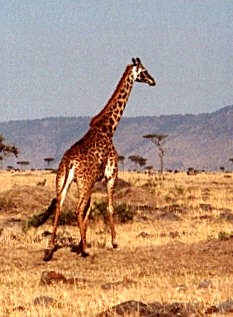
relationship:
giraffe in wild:
[34, 54, 166, 259] [1, 2, 231, 316]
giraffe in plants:
[34, 54, 166, 259] [0, 166, 233, 316]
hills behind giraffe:
[2, 101, 232, 166] [34, 54, 166, 259]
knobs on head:
[130, 56, 143, 65] [130, 64, 157, 84]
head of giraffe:
[130, 64, 157, 84] [34, 54, 166, 259]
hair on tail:
[30, 198, 58, 225] [30, 164, 71, 224]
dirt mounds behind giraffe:
[5, 175, 154, 218] [34, 54, 166, 259]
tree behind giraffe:
[141, 129, 169, 173] [34, 54, 166, 259]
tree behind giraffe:
[44, 158, 58, 171] [34, 54, 166, 259]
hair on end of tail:
[30, 198, 58, 225] [30, 164, 71, 224]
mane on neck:
[89, 65, 130, 126] [98, 74, 135, 140]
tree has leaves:
[141, 129, 169, 173] [142, 129, 167, 143]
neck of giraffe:
[98, 74, 135, 140] [34, 54, 166, 259]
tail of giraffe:
[30, 164, 71, 224] [34, 54, 166, 259]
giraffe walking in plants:
[34, 54, 166, 259] [0, 166, 233, 316]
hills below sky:
[2, 101, 232, 166] [0, 1, 230, 115]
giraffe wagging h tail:
[34, 54, 166, 259] [30, 164, 71, 224]